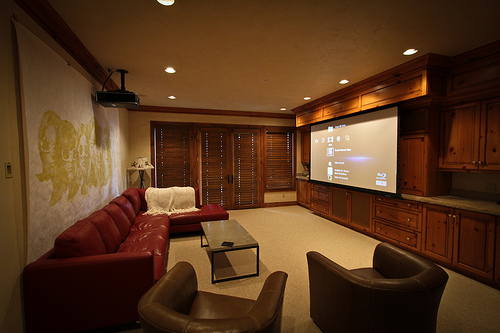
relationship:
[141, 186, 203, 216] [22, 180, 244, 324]
blanket in couch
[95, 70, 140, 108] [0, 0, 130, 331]
projector on a wall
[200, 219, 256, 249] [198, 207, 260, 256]
glass made of glass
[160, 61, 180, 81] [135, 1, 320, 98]
light on ceiling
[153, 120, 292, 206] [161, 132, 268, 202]
cabinets on window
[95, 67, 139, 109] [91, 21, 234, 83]
projector hanging ceiling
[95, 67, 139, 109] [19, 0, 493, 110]
projector hanging ceiling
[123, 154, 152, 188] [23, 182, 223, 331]
lamp behind couch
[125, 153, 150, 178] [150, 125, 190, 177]
lamp near window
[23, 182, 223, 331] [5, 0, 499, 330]
couch in a room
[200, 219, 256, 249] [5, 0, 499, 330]
glass in a room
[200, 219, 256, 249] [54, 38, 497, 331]
glass in room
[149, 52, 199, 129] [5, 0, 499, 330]
light in room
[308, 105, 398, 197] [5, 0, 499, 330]
projector screen in room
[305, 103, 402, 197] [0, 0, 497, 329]
projector screen in living room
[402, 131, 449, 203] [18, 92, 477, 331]
cabinet in a room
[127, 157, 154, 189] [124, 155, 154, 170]
lamp with a lamp shade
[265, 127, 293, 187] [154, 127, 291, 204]
blinds with blinds